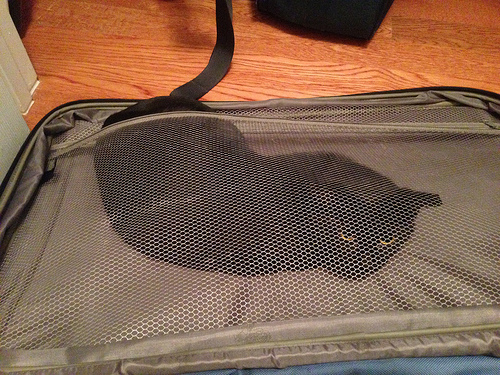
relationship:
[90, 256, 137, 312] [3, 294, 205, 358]
flap of bag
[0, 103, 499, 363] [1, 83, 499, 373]
flap of bag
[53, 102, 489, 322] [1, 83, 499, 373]
flap of bag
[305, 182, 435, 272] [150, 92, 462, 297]
head of cat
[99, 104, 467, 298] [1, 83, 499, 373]
cat inside bag